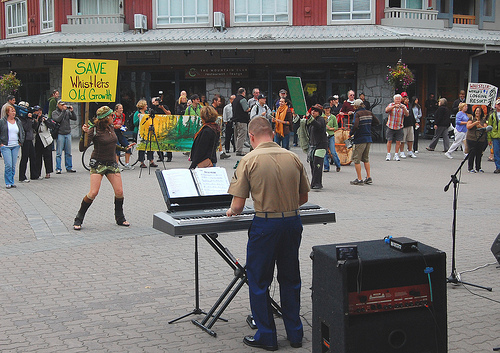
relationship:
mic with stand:
[441, 144, 487, 286] [447, 175, 459, 279]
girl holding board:
[72, 105, 130, 231] [61, 60, 112, 106]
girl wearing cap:
[72, 105, 130, 231] [96, 107, 114, 120]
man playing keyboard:
[225, 115, 309, 349] [152, 200, 337, 337]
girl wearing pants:
[72, 105, 130, 231] [208, 204, 327, 331]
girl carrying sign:
[72, 103, 133, 231] [52, 45, 134, 105]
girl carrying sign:
[72, 105, 130, 231] [61, 51, 116, 103]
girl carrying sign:
[72, 105, 130, 231] [57, 53, 122, 103]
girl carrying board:
[72, 105, 130, 231] [60, 57, 118, 103]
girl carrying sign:
[72, 103, 133, 231] [58, 48, 121, 103]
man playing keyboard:
[225, 116, 309, 350] [152, 195, 334, 237]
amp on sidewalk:
[310, 204, 462, 339] [2, 138, 497, 351]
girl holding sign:
[72, 105, 130, 231] [50, 45, 134, 111]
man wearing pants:
[225, 116, 309, 350] [228, 219, 332, 309]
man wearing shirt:
[225, 115, 309, 349] [221, 138, 313, 218]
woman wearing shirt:
[306, 92, 333, 194] [303, 112, 332, 151]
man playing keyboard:
[225, 115, 309, 349] [152, 199, 336, 235]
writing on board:
[67, 62, 115, 101] [60, 57, 118, 103]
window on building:
[157, 1, 170, 24] [4, 4, 499, 140]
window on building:
[167, 1, 183, 23] [4, 4, 499, 140]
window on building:
[182, 1, 194, 22] [4, 4, 499, 140]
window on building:
[196, 0, 209, 21] [4, 4, 499, 140]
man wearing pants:
[225, 116, 309, 350] [239, 210, 304, 351]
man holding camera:
[51, 100, 78, 171] [65, 104, 72, 109]